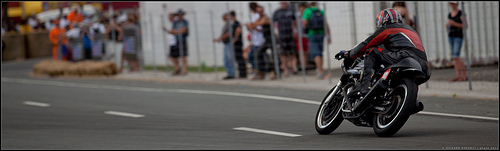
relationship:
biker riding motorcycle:
[333, 8, 435, 98] [316, 59, 421, 134]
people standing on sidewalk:
[158, 7, 192, 77] [122, 55, 494, 100]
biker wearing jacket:
[333, 8, 435, 98] [343, 22, 424, 60]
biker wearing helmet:
[333, 8, 435, 98] [372, 7, 402, 25]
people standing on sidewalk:
[153, 7, 209, 77] [200, 67, 318, 88]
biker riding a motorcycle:
[333, 8, 435, 98] [297, 28, 436, 142]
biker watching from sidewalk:
[333, 8, 435, 98] [36, 62, 496, 100]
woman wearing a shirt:
[445, 0, 468, 83] [449, 9, 465, 36]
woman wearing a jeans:
[445, 0, 468, 83] [449, 35, 461, 58]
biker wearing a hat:
[333, 8, 435, 98] [176, 7, 196, 23]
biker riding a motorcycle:
[333, 8, 435, 98] [311, 47, 426, 137]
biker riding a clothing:
[333, 8, 435, 98] [361, 22, 426, 62]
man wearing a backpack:
[298, 5, 328, 68] [292, 4, 362, 39]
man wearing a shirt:
[298, 5, 328, 68] [302, 7, 326, 45]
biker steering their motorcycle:
[333, 8, 435, 98] [311, 47, 426, 137]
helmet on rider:
[372, 6, 407, 31] [334, 7, 431, 97]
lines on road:
[66, 71, 237, 143] [38, 32, 495, 136]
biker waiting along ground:
[333, 8, 435, 98] [0, 56, 498, 150]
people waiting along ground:
[158, 7, 192, 77] [0, 56, 498, 150]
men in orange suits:
[43, 3, 87, 70] [47, 22, 85, 60]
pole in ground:
[456, 0, 474, 93] [0, 67, 498, 144]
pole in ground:
[267, 2, 279, 74] [0, 67, 498, 144]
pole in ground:
[326, 1, 330, 81] [0, 67, 498, 144]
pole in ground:
[207, 14, 217, 76] [0, 67, 498, 144]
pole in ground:
[160, 11, 167, 71] [0, 67, 498, 144]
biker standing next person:
[333, 8, 435, 98] [174, 5, 193, 73]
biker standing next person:
[333, 8, 435, 98] [226, 5, 251, 80]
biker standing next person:
[333, 8, 435, 98] [215, 7, 235, 81]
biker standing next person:
[333, 8, 435, 98] [206, 3, 251, 77]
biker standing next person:
[333, 8, 435, 98] [282, 0, 334, 69]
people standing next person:
[158, 7, 192, 77] [291, 0, 308, 70]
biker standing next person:
[333, 8, 435, 98] [65, 20, 84, 60]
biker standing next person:
[333, 8, 435, 98] [162, 12, 178, 79]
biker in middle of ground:
[336, 59, 454, 127] [0, 56, 498, 150]